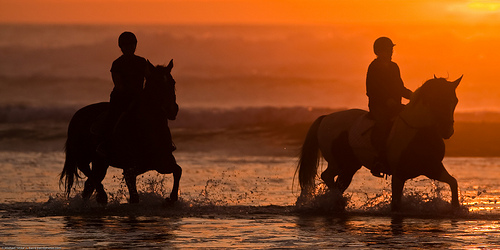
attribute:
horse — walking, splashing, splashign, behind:
[66, 58, 184, 208]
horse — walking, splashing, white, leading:
[304, 73, 462, 215]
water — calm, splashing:
[3, 80, 499, 246]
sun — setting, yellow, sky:
[443, 6, 495, 30]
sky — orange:
[4, 2, 497, 110]